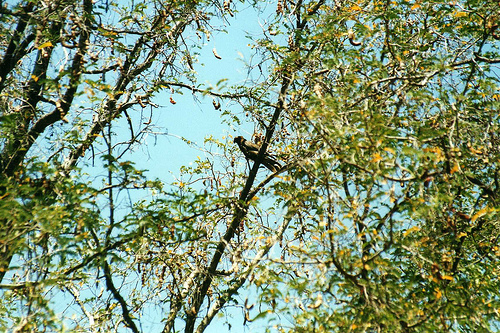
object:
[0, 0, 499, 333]
tree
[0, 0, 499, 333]
branch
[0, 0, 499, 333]
leaves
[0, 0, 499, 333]
sky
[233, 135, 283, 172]
bird